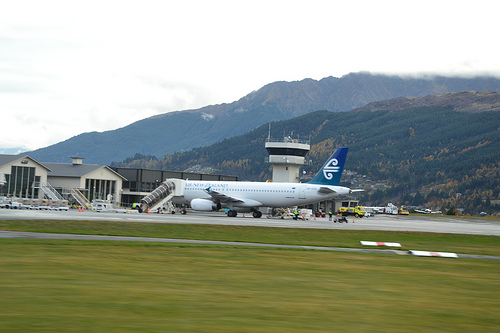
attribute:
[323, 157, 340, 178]
design — white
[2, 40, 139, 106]
clouds — white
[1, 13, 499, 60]
sky — blue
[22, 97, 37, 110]
cloud — white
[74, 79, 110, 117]
cloud — white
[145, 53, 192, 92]
cloud — white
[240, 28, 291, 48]
cloud — white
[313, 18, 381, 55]
cloud — white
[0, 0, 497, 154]
sky — blue, daytime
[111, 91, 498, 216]
mountain — background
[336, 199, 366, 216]
truck — yellow 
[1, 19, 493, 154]
sky — blue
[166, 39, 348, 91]
sky — blue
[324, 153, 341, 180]
design — white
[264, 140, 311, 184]
tower — white, black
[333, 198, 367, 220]
truck — yellow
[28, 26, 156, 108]
sky — blue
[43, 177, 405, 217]
cones — orange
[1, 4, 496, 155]
clouds — white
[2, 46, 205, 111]
clouds — white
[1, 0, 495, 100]
sky — blue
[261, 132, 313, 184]
tower — behind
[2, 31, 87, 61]
cloud — white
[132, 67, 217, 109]
cloud — white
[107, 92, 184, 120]
cloud — white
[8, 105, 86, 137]
cloud — white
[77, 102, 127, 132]
cloud — white